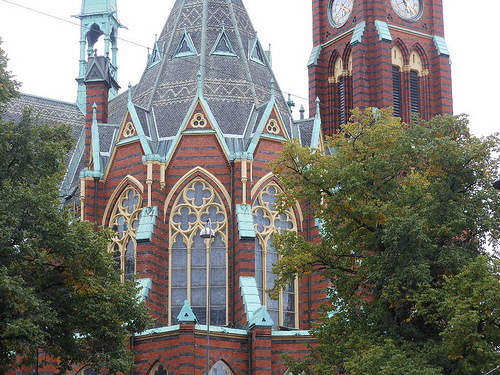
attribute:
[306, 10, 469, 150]
tower — double-sided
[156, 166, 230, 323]
window — golden, arched, large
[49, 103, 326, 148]
roof — steep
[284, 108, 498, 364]
tree — large, tall, green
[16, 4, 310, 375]
church — red, brick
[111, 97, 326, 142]
trim — green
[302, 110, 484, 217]
leaves — green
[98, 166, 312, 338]
windows — arched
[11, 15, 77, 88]
sky — white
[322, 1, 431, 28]
clocks — white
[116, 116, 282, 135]
windows — small